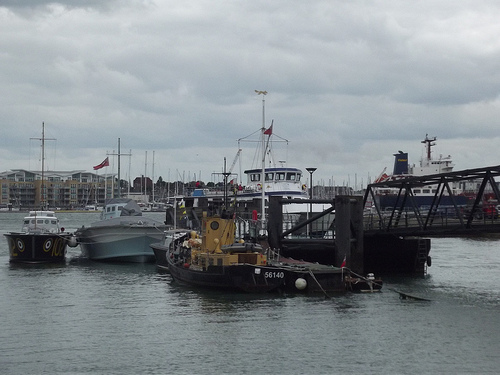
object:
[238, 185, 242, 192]
person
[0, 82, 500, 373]
port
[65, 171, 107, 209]
buildings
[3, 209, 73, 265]
boat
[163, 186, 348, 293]
boat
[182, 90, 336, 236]
ship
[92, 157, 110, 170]
flag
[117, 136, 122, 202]
pole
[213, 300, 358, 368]
water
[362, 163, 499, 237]
black walkway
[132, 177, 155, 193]
house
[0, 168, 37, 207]
building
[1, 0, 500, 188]
cloudy sky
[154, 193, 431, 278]
dock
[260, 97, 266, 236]
pole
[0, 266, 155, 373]
water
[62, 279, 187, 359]
ripples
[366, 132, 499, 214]
boat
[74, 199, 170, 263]
boat